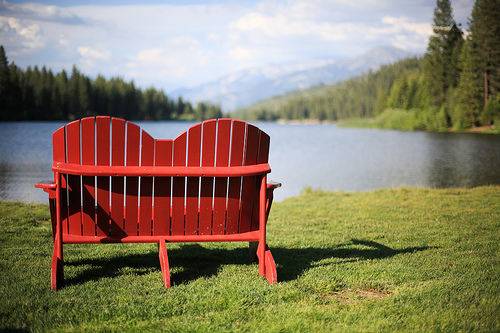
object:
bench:
[34, 115, 282, 290]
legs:
[47, 244, 65, 291]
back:
[61, 160, 267, 236]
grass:
[0, 186, 498, 333]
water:
[2, 120, 499, 206]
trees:
[441, 0, 500, 126]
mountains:
[209, 46, 403, 115]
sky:
[0, 1, 500, 95]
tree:
[152, 88, 170, 118]